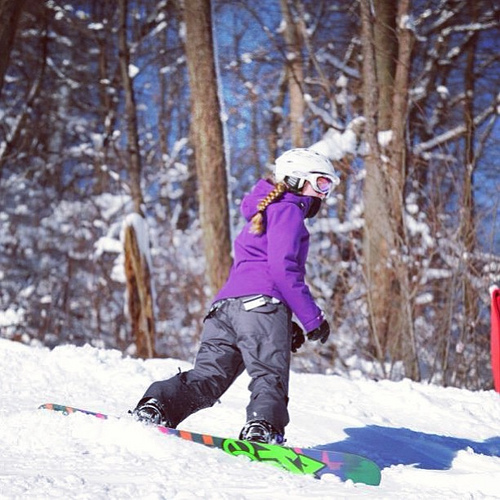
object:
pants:
[144, 297, 299, 442]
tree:
[460, 3, 497, 354]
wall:
[442, 127, 475, 146]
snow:
[0, 330, 484, 500]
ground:
[0, 355, 499, 499]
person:
[126, 147, 338, 444]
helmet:
[276, 150, 339, 191]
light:
[410, 288, 444, 333]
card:
[241, 292, 266, 309]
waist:
[212, 290, 287, 299]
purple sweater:
[209, 173, 326, 333]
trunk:
[183, 0, 233, 301]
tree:
[180, 1, 235, 296]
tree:
[116, 2, 156, 359]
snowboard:
[39, 400, 381, 488]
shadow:
[332, 405, 498, 480]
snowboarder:
[189, 117, 391, 496]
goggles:
[312, 174, 339, 194]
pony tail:
[246, 174, 288, 239]